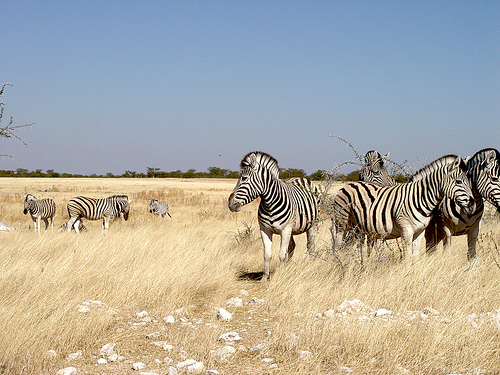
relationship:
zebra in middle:
[362, 153, 394, 182] [352, 144, 405, 196]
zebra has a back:
[226, 151, 318, 280] [280, 175, 309, 186]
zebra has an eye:
[226, 151, 318, 280] [240, 174, 248, 181]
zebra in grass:
[226, 151, 318, 280] [2, 176, 498, 374]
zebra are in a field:
[226, 151, 318, 280] [1, 175, 498, 374]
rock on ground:
[216, 307, 233, 320] [2, 175, 499, 374]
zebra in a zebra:
[226, 151, 318, 280] [226, 151, 318, 284]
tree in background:
[147, 166, 160, 176] [3, 124, 499, 181]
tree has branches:
[147, 166, 160, 176] [2, 82, 35, 160]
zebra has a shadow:
[226, 151, 318, 280] [240, 271, 266, 282]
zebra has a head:
[226, 151, 318, 280] [228, 151, 281, 212]